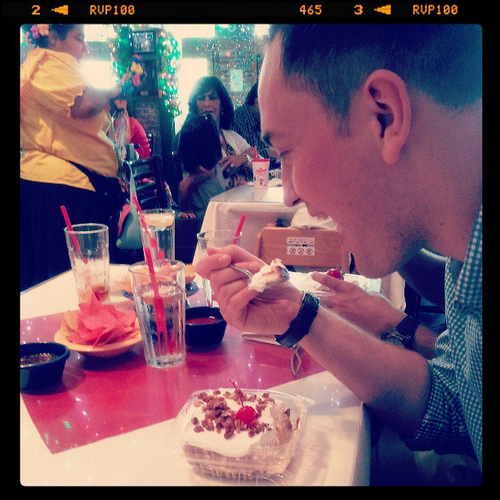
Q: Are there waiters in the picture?
A: No, there are no waiters.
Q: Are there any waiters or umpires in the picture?
A: No, there are no waiters or umpires.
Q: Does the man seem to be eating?
A: Yes, the man is eating.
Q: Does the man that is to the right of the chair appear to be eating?
A: Yes, the man is eating.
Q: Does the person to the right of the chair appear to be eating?
A: Yes, the man is eating.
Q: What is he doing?
A: The man is eating.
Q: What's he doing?
A: The man is eating.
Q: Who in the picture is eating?
A: The man is eating.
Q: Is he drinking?
A: No, the man is eating.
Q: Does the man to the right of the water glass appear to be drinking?
A: No, the man is eating.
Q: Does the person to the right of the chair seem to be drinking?
A: No, the man is eating.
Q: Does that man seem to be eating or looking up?
A: The man is eating.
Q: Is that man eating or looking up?
A: The man is eating.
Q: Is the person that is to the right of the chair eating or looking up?
A: The man is eating.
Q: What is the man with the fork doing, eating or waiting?
A: The man is eating.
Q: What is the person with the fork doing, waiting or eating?
A: The man is eating.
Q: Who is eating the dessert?
A: The man is eating the dessert.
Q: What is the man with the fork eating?
A: The man is eating a dessert.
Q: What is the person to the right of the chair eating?
A: The man is eating a dessert.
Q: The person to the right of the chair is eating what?
A: The man is eating a dessert.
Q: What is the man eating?
A: The man is eating a dessert.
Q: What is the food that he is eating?
A: The food is a dessert.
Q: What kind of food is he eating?
A: The man is eating a dessert.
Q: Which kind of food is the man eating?
A: The man is eating a dessert.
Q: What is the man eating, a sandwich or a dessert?
A: The man is eating a dessert.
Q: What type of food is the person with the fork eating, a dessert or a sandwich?
A: The man is eating a dessert.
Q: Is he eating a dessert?
A: Yes, the man is eating a dessert.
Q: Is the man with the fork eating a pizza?
A: No, the man is eating a dessert.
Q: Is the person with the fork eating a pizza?
A: No, the man is eating a dessert.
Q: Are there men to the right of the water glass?
A: Yes, there is a man to the right of the water glass.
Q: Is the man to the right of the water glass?
A: Yes, the man is to the right of the water glass.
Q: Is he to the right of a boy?
A: No, the man is to the right of the water glass.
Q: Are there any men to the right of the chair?
A: Yes, there is a man to the right of the chair.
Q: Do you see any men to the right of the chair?
A: Yes, there is a man to the right of the chair.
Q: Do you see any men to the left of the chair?
A: No, the man is to the right of the chair.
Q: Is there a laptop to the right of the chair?
A: No, there is a man to the right of the chair.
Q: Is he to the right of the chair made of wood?
A: Yes, the man is to the right of the chair.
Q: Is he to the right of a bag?
A: No, the man is to the right of the chair.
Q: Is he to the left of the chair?
A: No, the man is to the right of the chair.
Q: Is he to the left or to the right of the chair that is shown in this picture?
A: The man is to the right of the chair.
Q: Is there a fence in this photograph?
A: No, there are no fences.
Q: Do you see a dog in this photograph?
A: No, there are no dogs.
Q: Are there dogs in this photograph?
A: No, there are no dogs.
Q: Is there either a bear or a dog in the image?
A: No, there are no dogs or bears.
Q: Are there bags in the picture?
A: No, there are no bags.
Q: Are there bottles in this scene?
A: No, there are no bottles.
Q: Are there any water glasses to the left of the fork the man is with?
A: Yes, there is a water glass to the left of the fork.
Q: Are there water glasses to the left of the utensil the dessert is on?
A: Yes, there is a water glass to the left of the fork.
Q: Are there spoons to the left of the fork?
A: No, there is a water glass to the left of the fork.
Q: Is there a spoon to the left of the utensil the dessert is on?
A: No, there is a water glass to the left of the fork.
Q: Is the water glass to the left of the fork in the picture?
A: Yes, the water glass is to the left of the fork.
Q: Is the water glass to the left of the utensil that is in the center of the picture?
A: Yes, the water glass is to the left of the fork.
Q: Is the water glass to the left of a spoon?
A: No, the water glass is to the left of the fork.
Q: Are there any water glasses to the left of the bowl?
A: Yes, there is a water glass to the left of the bowl.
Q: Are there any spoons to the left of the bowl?
A: No, there is a water glass to the left of the bowl.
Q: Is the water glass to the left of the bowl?
A: Yes, the water glass is to the left of the bowl.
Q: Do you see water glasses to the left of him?
A: Yes, there is a water glass to the left of the man.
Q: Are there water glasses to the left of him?
A: Yes, there is a water glass to the left of the man.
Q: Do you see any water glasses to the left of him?
A: Yes, there is a water glass to the left of the man.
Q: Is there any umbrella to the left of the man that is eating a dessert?
A: No, there is a water glass to the left of the man.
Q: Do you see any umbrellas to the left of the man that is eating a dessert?
A: No, there is a water glass to the left of the man.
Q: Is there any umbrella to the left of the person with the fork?
A: No, there is a water glass to the left of the man.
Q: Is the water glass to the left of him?
A: Yes, the water glass is to the left of a man.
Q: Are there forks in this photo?
A: Yes, there is a fork.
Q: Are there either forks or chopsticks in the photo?
A: Yes, there is a fork.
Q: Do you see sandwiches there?
A: No, there are no sandwiches.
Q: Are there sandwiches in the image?
A: No, there are no sandwiches.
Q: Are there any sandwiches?
A: No, there are no sandwiches.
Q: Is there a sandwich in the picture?
A: No, there are no sandwiches.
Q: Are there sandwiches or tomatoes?
A: No, there are no sandwiches or tomatoes.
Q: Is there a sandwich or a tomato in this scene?
A: No, there are no sandwiches or tomatoes.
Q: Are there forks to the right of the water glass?
A: Yes, there is a fork to the right of the water glass.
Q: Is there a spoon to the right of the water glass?
A: No, there is a fork to the right of the water glass.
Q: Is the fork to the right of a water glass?
A: Yes, the fork is to the right of a water glass.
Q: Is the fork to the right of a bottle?
A: No, the fork is to the right of a water glass.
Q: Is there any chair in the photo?
A: Yes, there is a chair.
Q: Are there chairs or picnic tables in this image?
A: Yes, there is a chair.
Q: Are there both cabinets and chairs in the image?
A: No, there is a chair but no cabinets.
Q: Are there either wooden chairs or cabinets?
A: Yes, there is a wood chair.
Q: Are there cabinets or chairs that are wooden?
A: Yes, the chair is wooden.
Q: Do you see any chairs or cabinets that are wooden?
A: Yes, the chair is wooden.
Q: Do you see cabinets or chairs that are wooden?
A: Yes, the chair is wooden.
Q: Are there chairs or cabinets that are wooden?
A: Yes, the chair is wooden.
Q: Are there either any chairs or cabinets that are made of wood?
A: Yes, the chair is made of wood.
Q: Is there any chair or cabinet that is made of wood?
A: Yes, the chair is made of wood.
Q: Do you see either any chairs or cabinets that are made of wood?
A: Yes, the chair is made of wood.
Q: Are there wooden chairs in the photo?
A: Yes, there is a wood chair.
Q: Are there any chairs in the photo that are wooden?
A: Yes, there is a chair that is wooden.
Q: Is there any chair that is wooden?
A: Yes, there is a chair that is wooden.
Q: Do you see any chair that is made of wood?
A: Yes, there is a chair that is made of wood.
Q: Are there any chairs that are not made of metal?
A: Yes, there is a chair that is made of wood.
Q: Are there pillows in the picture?
A: No, there are no pillows.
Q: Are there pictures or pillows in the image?
A: No, there are no pillows or pictures.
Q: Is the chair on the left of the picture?
A: Yes, the chair is on the left of the image.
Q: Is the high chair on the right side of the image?
A: No, the chair is on the left of the image.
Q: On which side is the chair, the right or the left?
A: The chair is on the left of the image.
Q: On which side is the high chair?
A: The chair is on the left of the image.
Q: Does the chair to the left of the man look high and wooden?
A: Yes, the chair is high and wooden.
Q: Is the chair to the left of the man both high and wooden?
A: Yes, the chair is high and wooden.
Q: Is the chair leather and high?
A: No, the chair is high but wooden.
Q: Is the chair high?
A: Yes, the chair is high.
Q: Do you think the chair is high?
A: Yes, the chair is high.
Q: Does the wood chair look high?
A: Yes, the chair is high.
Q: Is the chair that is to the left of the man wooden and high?
A: Yes, the chair is wooden and high.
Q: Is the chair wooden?
A: Yes, the chair is wooden.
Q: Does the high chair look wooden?
A: Yes, the chair is wooden.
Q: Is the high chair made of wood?
A: Yes, the chair is made of wood.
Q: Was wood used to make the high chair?
A: Yes, the chair is made of wood.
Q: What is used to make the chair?
A: The chair is made of wood.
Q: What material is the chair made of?
A: The chair is made of wood.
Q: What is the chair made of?
A: The chair is made of wood.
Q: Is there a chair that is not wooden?
A: No, there is a chair but it is wooden.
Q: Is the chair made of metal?
A: No, the chair is made of wood.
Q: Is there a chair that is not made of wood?
A: No, there is a chair but it is made of wood.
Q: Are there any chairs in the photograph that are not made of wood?
A: No, there is a chair but it is made of wood.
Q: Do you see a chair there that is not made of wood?
A: No, there is a chair but it is made of wood.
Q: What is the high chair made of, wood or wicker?
A: The chair is made of wood.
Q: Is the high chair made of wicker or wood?
A: The chair is made of wood.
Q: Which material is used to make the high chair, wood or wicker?
A: The chair is made of wood.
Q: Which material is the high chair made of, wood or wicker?
A: The chair is made of wood.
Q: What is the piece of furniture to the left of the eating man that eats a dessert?
A: The piece of furniture is a chair.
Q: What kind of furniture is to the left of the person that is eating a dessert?
A: The piece of furniture is a chair.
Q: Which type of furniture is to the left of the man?
A: The piece of furniture is a chair.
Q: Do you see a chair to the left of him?
A: Yes, there is a chair to the left of the man.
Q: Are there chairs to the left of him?
A: Yes, there is a chair to the left of the man.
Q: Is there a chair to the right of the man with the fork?
A: No, the chair is to the left of the man.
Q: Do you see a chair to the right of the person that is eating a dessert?
A: No, the chair is to the left of the man.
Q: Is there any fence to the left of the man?
A: No, there is a chair to the left of the man.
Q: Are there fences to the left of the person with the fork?
A: No, there is a chair to the left of the man.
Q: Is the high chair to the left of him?
A: Yes, the chair is to the left of a man.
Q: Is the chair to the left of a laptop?
A: No, the chair is to the left of a man.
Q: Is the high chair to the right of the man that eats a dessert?
A: No, the chair is to the left of the man.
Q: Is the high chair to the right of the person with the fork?
A: No, the chair is to the left of the man.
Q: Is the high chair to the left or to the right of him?
A: The chair is to the left of the man.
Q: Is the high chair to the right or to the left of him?
A: The chair is to the left of the man.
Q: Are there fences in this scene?
A: No, there are no fences.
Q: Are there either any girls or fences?
A: No, there are no fences or girls.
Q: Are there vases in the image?
A: No, there are no vases.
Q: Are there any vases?
A: No, there are no vases.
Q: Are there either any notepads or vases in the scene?
A: No, there are no vases or notepads.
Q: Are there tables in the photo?
A: Yes, there is a table.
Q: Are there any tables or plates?
A: Yes, there is a table.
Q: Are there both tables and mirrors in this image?
A: No, there is a table but no mirrors.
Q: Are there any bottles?
A: No, there are no bottles.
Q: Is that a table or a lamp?
A: That is a table.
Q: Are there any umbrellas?
A: No, there are no umbrellas.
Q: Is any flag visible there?
A: No, there are no flags.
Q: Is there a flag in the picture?
A: No, there are no flags.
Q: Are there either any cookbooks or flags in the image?
A: No, there are no flags or cookbooks.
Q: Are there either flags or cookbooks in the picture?
A: No, there are no flags or cookbooks.